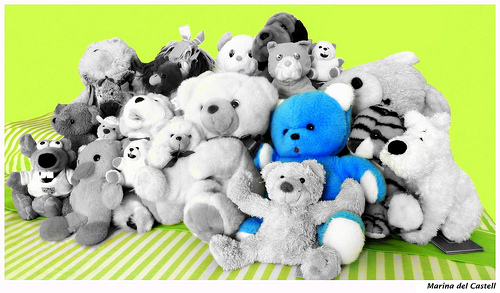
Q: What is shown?
A: Stuffed animals.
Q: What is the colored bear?
A: Blue.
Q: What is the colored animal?
A: Bear.